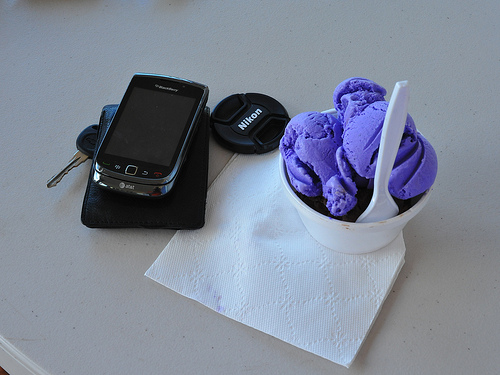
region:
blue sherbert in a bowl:
[275, 66, 437, 259]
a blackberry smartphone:
[97, 47, 209, 209]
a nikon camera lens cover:
[206, 82, 298, 159]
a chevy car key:
[43, 117, 101, 197]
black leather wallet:
[86, 81, 219, 256]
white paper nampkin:
[135, 147, 420, 373]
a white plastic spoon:
[346, 83, 423, 275]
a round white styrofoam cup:
[270, 128, 440, 259]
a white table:
[35, 265, 130, 345]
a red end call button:
[151, 168, 163, 177]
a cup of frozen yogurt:
[282, 69, 440, 251]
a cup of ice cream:
[270, 65, 455, 243]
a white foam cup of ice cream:
[268, 81, 465, 272]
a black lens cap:
[212, 83, 297, 154]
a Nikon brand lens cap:
[209, 84, 294, 166]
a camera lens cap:
[205, 87, 303, 179]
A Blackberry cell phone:
[89, 39, 209, 207]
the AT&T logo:
[107, 180, 143, 194]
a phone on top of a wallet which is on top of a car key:
[26, 45, 223, 235]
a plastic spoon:
[352, 74, 423, 230]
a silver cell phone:
[66, 57, 212, 200]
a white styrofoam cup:
[268, 87, 443, 304]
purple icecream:
[279, 71, 451, 218]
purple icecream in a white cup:
[276, 70, 453, 298]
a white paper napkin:
[155, 110, 457, 374]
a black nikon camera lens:
[196, 74, 311, 166]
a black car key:
[36, 117, 124, 201]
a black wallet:
[57, 89, 228, 269]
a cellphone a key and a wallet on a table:
[37, 63, 233, 243]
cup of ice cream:
[282, 71, 427, 255]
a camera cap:
[211, 84, 278, 154]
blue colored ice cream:
[287, 78, 430, 249]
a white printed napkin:
[205, 255, 381, 356]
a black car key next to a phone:
[46, 117, 86, 172]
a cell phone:
[95, 72, 200, 192]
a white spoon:
[363, 77, 404, 223]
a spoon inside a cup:
[290, 72, 420, 248]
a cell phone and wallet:
[87, 61, 212, 228]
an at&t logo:
[110, 173, 142, 196]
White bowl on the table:
[278, 102, 437, 254]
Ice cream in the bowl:
[278, 77, 437, 217]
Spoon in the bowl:
[356, 80, 411, 220]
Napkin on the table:
[142, 151, 404, 368]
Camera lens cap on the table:
[209, 91, 289, 153]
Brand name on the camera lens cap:
[234, 105, 265, 132]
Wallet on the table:
[78, 93, 210, 231]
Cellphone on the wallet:
[91, 71, 211, 200]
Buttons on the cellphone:
[98, 156, 164, 181]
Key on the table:
[46, 124, 99, 189]